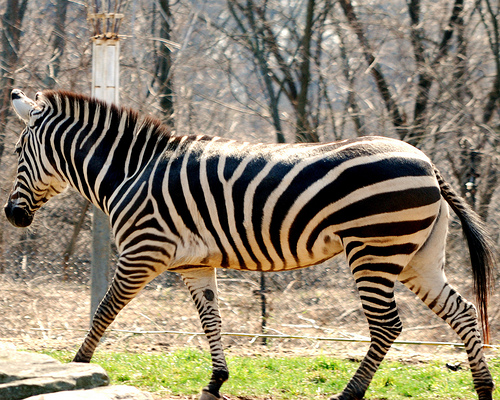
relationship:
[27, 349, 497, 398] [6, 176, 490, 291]
grass in fence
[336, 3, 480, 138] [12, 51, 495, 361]
trees outside enclosure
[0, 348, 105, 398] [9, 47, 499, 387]
rock inside zoo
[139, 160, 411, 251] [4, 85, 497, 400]
pattern on zebra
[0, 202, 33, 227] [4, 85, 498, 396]
snout of zebra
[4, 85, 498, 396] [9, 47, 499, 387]
zebra in zoo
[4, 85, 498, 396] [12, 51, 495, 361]
zebra in enclosure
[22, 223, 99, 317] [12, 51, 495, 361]
chain link bordering enclosure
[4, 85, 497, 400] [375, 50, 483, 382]
zebra looking away from camera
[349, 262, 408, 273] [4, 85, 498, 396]
black stripe on zebra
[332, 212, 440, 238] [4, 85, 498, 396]
black stripe on zebra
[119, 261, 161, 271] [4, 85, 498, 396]
black stripe on zebra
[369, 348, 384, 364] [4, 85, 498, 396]
black stripe on zebra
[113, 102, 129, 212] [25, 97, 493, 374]
stripe on zebra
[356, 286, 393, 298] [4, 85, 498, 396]
stripe on zebra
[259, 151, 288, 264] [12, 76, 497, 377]
stripe on zebra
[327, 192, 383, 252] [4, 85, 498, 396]
stripe on zebra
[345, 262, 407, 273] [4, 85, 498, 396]
black stripe on zebra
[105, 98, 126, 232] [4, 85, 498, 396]
stripe on zebra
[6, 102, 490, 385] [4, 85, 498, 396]
stripe is on zebra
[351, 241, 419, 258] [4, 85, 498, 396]
stripe is on zebra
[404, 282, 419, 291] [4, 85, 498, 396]
stripe is on zebra